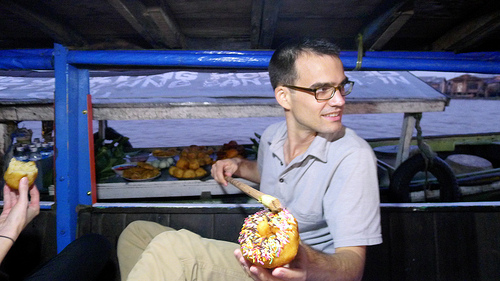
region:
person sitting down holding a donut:
[110, 28, 392, 279]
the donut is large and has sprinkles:
[234, 200, 302, 274]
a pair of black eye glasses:
[282, 73, 359, 101]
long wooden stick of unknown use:
[219, 171, 284, 212]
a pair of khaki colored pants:
[114, 219, 257, 279]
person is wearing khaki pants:
[102, 33, 388, 279]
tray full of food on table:
[165, 157, 207, 181]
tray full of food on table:
[118, 159, 166, 181]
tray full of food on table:
[145, 150, 177, 170]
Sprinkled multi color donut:
[237, 207, 301, 269]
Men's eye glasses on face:
[283, 77, 356, 102]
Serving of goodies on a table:
[112, 142, 213, 180]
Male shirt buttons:
[277, 157, 288, 185]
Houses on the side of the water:
[446, 72, 498, 97]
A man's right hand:
[206, 154, 261, 189]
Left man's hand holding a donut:
[233, 207, 368, 279]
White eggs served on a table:
[143, 152, 174, 169]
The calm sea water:
[452, 92, 499, 127]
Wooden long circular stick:
[210, 174, 285, 214]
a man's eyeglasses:
[277, 78, 358, 100]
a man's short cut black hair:
[265, 37, 345, 94]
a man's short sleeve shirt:
[257, 122, 383, 262]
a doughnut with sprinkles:
[240, 208, 300, 266]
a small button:
[274, 177, 285, 184]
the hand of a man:
[209, 155, 241, 185]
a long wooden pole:
[222, 170, 281, 210]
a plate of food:
[117, 160, 162, 179]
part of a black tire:
[388, 155, 460, 207]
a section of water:
[426, 98, 498, 138]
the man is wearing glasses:
[270, 48, 366, 113]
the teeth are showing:
[311, 106, 348, 128]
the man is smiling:
[312, 97, 352, 129]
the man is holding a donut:
[192, 166, 319, 273]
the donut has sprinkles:
[207, 172, 322, 277]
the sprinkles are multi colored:
[223, 187, 298, 257]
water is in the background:
[176, 102, 486, 144]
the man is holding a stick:
[193, 144, 293, 222]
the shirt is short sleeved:
[216, 117, 395, 258]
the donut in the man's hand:
[239, 205, 299, 267]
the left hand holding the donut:
[233, 200, 311, 280]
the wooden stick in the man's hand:
[223, 172, 280, 211]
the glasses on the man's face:
[277, 80, 354, 98]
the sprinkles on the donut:
[237, 206, 294, 265]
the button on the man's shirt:
[278, 177, 283, 182]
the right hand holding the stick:
[207, 158, 240, 184]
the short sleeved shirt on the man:
[251, 116, 381, 255]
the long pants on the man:
[116, 219, 256, 279]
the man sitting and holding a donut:
[116, 36, 382, 278]